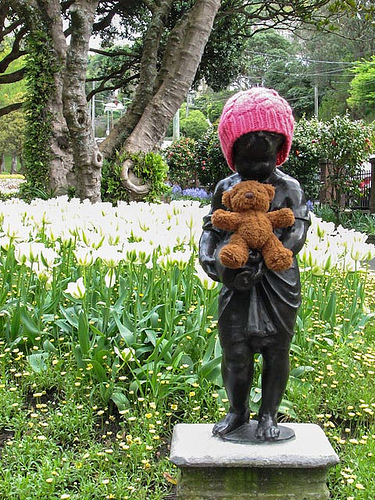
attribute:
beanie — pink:
[217, 88, 296, 173]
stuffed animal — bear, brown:
[210, 182, 295, 272]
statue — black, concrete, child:
[199, 86, 310, 444]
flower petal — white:
[66, 277, 85, 298]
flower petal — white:
[99, 249, 122, 268]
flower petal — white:
[42, 249, 58, 265]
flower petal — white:
[73, 249, 97, 265]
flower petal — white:
[24, 244, 38, 260]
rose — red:
[201, 167, 206, 172]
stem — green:
[349, 280, 361, 325]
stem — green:
[75, 314, 91, 361]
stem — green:
[133, 286, 141, 345]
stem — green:
[13, 269, 23, 348]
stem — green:
[104, 290, 113, 347]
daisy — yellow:
[351, 244, 366, 264]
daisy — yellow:
[318, 252, 334, 275]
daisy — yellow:
[123, 245, 144, 263]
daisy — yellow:
[174, 247, 191, 273]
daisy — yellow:
[159, 236, 180, 250]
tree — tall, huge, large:
[61, 0, 105, 204]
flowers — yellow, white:
[5, 215, 23, 235]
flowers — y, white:
[84, 227, 107, 245]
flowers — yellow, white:
[139, 212, 160, 230]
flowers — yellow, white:
[117, 221, 135, 235]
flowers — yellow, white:
[183, 215, 199, 228]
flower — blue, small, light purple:
[196, 190, 207, 199]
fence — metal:
[336, 169, 372, 208]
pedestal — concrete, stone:
[171, 419, 340, 499]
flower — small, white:
[178, 232, 192, 244]